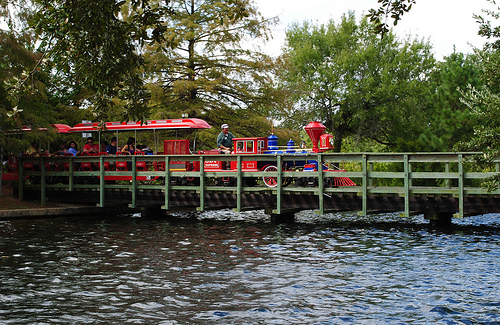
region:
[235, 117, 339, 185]
red and blue engine of train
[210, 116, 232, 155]
engineer on train cart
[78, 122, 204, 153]
red and white shuttle car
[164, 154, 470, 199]
green wooden bridge posts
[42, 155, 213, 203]
green wooden bridge posts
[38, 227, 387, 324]
grayish green water under bridge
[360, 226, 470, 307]
grayish green water under bridge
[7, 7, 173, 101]
brown trees with green leaves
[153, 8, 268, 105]
brown trees with green leaves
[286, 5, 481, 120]
brown trees with green leaves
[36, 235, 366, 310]
Rippling water with sunlight highlights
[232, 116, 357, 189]
Train engine crossing the bridge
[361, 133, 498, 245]
Bridge spanning moving water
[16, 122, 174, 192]
Passengers on mini train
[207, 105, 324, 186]
Train Engineer wearing a cap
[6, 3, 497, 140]
Variety of trees in the background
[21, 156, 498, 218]
Green wooden railings span the bridge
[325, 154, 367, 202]
Bright red cowcatcher on front of engine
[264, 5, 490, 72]
Trees reaching up to the sunlit sky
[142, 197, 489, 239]
Bridge supports with tops just out of water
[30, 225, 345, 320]
rippling surface of water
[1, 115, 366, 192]
red train with passengers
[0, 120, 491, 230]
red train going across bridge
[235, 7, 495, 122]
green trees against sky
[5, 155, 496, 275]
a bridge across water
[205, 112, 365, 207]
conductor of train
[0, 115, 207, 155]
passengers on train ride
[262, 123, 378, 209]
engine compartment of train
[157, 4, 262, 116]
yellowish green tree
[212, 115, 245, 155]
man wearing a hat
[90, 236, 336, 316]
clear dark water under the bridge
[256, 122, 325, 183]
blue piece of the train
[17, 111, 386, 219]
a red train on the bridge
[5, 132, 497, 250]
a bridge over the water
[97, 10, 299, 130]
a yellow tree next to the train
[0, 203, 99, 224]
concrete curb under the bridge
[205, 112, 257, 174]
a man driving the train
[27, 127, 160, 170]
people riding on the train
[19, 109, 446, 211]
a train moving across the train tracks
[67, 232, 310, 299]
ripples in the water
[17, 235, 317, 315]
flow of calm water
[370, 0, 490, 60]
cloudy sky through trees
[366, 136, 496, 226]
a wooden bridge spanning water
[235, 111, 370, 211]
a small train engine crossing a bridge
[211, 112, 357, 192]
train engineer at work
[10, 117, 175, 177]
tourists on a train ride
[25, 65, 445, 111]
thickly wooded area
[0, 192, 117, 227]
bank at water's edge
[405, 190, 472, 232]
bridge support with track above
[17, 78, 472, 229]
miniature train ride crosses a body of water